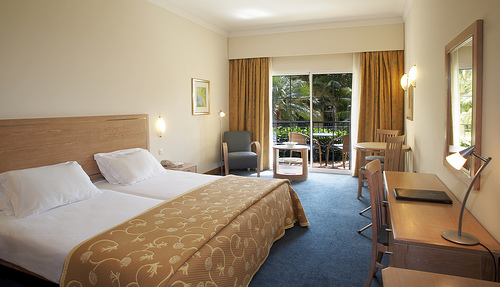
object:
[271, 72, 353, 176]
window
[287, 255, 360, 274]
carpet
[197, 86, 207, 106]
picture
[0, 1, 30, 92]
wall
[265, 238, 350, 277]
floor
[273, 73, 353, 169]
glass door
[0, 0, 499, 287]
motel room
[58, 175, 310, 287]
blanket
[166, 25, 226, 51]
wall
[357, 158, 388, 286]
chair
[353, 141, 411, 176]
chair table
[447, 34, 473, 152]
mirror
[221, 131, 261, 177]
chair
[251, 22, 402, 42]
wall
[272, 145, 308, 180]
table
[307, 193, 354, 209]
carpet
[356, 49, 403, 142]
gold drapes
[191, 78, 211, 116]
frame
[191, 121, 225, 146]
wall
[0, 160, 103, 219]
pillow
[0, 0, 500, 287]
room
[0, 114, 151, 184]
head board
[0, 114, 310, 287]
bed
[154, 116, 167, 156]
lamp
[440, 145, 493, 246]
lamp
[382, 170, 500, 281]
dresser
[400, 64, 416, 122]
fixture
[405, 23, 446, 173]
wall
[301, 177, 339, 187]
carpeting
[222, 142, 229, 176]
arms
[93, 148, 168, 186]
pillow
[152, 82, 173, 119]
wall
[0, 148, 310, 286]
comforter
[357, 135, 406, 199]
chair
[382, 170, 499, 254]
table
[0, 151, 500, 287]
foreground